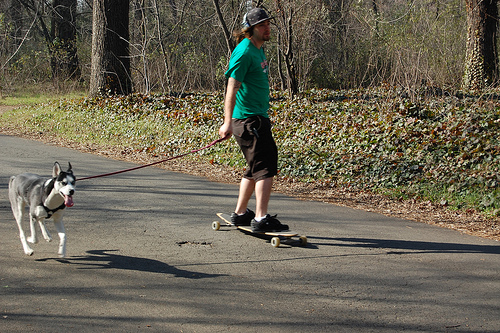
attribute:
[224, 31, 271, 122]
shirt — green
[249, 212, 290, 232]
shoe — black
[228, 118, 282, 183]
shorts — brown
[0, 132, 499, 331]
road — grey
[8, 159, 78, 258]
grey dog — white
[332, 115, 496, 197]
leaves — green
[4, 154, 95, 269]
dog — walking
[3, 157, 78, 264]
dog — black, white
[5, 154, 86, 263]
dog — running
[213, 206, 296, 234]
board — long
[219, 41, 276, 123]
shirt — green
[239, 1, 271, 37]
cap — black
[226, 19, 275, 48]
hair — long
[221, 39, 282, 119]
shirt — green 